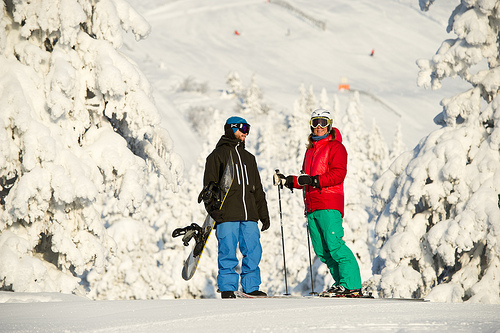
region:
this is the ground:
[224, 298, 297, 328]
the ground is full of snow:
[238, 298, 299, 330]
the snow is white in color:
[193, 302, 244, 321]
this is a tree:
[8, 3, 163, 306]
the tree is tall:
[23, 5, 157, 292]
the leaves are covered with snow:
[38, 154, 125, 216]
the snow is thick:
[53, 152, 102, 185]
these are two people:
[175, 106, 378, 292]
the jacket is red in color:
[318, 143, 329, 164]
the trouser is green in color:
[316, 216, 328, 230]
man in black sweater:
[168, 90, 263, 298]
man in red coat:
[310, 55, 352, 313]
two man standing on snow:
[170, 105, 405, 331]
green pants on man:
[308, 215, 373, 302]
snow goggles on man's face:
[293, 109, 345, 144]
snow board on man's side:
[177, 178, 230, 305]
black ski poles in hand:
[256, 144, 323, 301]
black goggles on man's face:
[223, 116, 253, 142]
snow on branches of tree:
[57, 71, 129, 191]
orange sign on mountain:
[306, 63, 377, 113]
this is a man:
[287, 110, 379, 287]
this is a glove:
[298, 170, 318, 187]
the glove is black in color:
[301, 177, 313, 182]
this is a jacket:
[310, 149, 330, 166]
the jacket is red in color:
[311, 150, 345, 165]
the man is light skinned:
[313, 128, 335, 133]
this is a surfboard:
[211, 165, 237, 211]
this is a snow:
[34, 60, 124, 165]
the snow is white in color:
[35, 75, 78, 179]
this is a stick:
[278, 185, 293, 275]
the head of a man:
[202, 117, 266, 162]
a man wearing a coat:
[293, 114, 367, 205]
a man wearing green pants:
[294, 220, 382, 307]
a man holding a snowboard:
[158, 110, 281, 285]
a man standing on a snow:
[280, 77, 411, 298]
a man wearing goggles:
[214, 106, 272, 143]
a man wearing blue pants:
[195, 193, 314, 300]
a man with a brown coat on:
[172, 65, 312, 235]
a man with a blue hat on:
[211, 90, 276, 150]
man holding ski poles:
[277, 110, 416, 300]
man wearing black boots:
[278, 109, 370, 295]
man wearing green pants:
[275, 113, 370, 296]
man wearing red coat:
[275, 110, 367, 294]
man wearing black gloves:
[276, 109, 364, 296]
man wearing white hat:
[280, 107, 364, 297]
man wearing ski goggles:
[275, 108, 364, 298]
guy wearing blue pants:
[172, 116, 272, 298]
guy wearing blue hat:
[170, 117, 276, 296]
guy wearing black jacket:
[175, 119, 272, 300]